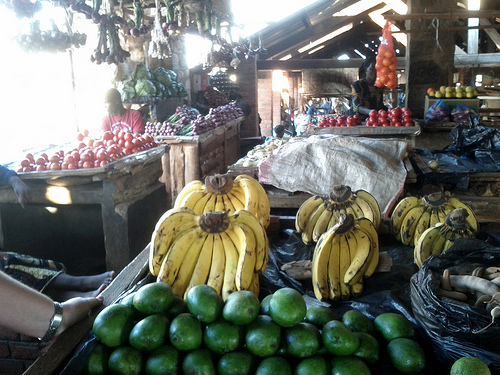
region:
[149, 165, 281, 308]
yellow bananas in basketg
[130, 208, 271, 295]
bunch of bananas together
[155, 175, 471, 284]
six bunches of bananas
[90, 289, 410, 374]
green limes stacked up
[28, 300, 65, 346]
silver bracelet on woman's wrist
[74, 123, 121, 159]
red apples stacked up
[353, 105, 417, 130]
red apples stacked together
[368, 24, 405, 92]
oranges hanging in a bag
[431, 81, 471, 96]
yellow apples in the back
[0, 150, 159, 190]
grey crate of food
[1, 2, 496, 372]
a produce market displaying its wares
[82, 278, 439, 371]
avocados in a pyramid for sale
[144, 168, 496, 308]
really big bunches of bananas for sale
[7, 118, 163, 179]
a big bin of tomatoes for sale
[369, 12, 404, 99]
a bag of oranges on display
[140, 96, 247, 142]
this look like some kind of onions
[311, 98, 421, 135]
red apples in big piles for sale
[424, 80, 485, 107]
these look like jumbo golden apples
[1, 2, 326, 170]
it's a bright sunny day outside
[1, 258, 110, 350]
a prospective buyer looking at the goods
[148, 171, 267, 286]
two bunches of bananas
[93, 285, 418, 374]
green mangos stacked on one another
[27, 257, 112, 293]
two legs crossed and resting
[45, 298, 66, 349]
silver watch around a wrist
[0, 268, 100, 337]
human arm and hand leaning on shelf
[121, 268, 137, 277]
wood used to make shelf for fruit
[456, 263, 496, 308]
items that are probably edible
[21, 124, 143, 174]
stack of red tomatoes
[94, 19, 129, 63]
items hanging from ceiling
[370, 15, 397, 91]
orange bag of oranges hanging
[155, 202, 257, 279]
bananas in a bunch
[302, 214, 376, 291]
bananas in a bunch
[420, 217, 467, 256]
bananas in a bunch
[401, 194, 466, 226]
bananas in a bunch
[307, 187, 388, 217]
bananas in a bunch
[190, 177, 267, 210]
bananas in a bunch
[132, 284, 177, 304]
fruit in a stack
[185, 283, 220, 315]
fruit in a stack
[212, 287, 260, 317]
fruit in a stack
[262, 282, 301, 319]
fruit in a stack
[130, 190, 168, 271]
banana on a cart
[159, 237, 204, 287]
banana on a cart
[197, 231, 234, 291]
banana on a cart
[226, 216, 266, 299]
banana on a cart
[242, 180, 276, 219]
banana on a cart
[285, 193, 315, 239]
banana on a cart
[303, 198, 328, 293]
banana on a cart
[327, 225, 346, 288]
banana on a cart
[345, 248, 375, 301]
banana on a cart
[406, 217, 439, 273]
banana on a cart